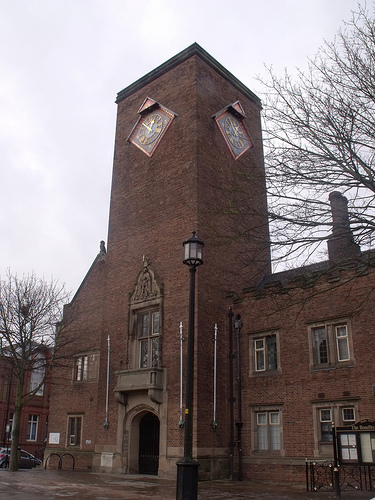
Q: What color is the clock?
A: Brown.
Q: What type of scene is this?
A: Outdoor.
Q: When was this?
A: Daytime.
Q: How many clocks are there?
A: Two.